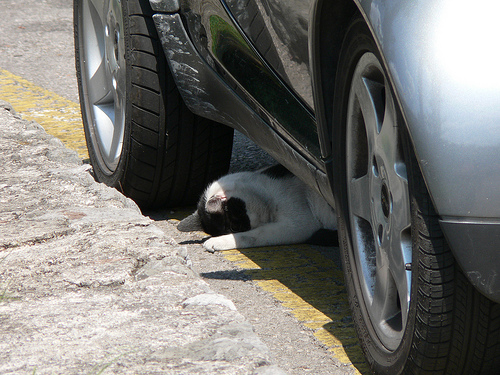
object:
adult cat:
[176, 164, 340, 251]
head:
[175, 166, 276, 245]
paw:
[202, 235, 232, 253]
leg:
[216, 224, 313, 250]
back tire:
[66, 1, 232, 211]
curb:
[43, 157, 235, 369]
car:
[70, 0, 499, 375]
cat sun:
[185, 191, 261, 256]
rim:
[342, 50, 414, 352]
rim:
[75, 0, 128, 179]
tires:
[70, 0, 234, 213]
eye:
[224, 206, 229, 212]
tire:
[323, 42, 482, 374]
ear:
[176, 211, 204, 231]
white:
[274, 193, 308, 230]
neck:
[229, 169, 284, 210]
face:
[198, 192, 251, 237]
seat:
[231, 5, 321, 132]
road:
[2, 2, 369, 371]